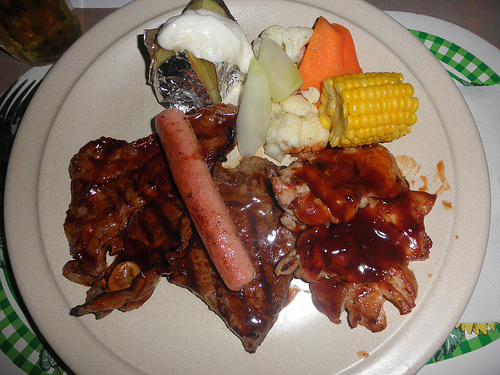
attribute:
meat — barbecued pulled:
[285, 169, 415, 304]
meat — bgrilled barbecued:
[92, 116, 424, 333]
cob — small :
[323, 74, 418, 142]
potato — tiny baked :
[246, 66, 324, 156]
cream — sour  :
[161, 8, 247, 60]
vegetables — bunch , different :
[214, 38, 408, 161]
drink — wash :
[9, 1, 72, 69]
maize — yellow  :
[322, 70, 418, 149]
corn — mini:
[319, 72, 419, 148]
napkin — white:
[461, 86, 499, 322]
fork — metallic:
[1, 77, 37, 169]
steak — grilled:
[61, 104, 290, 354]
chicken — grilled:
[286, 144, 435, 333]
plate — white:
[9, 142, 469, 372]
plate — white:
[42, 0, 459, 373]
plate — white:
[50, 309, 422, 372]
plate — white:
[287, 320, 404, 372]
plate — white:
[281, 330, 393, 372]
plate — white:
[141, 315, 229, 373]